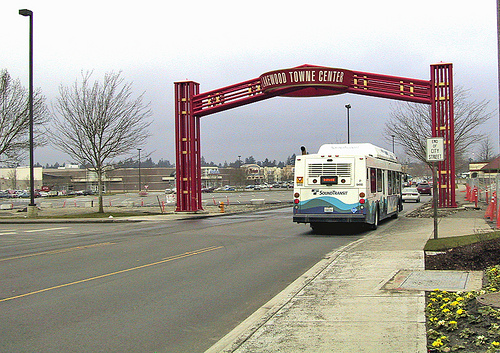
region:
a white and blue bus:
[294, 133, 397, 223]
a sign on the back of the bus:
[325, 171, 342, 182]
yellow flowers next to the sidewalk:
[429, 283, 499, 346]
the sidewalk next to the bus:
[297, 230, 403, 337]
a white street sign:
[428, 133, 447, 236]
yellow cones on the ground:
[53, 191, 198, 205]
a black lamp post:
[20, 8, 40, 213]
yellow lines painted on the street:
[16, 245, 215, 302]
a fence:
[466, 175, 495, 200]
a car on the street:
[404, 182, 419, 199]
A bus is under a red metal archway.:
[167, 57, 463, 233]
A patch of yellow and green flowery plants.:
[416, 265, 498, 351]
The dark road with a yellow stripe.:
[1, 207, 328, 351]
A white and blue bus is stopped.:
[287, 140, 415, 237]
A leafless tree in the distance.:
[46, 64, 161, 217]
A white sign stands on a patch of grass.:
[422, 132, 449, 250]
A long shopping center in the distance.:
[2, 163, 294, 191]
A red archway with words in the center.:
[171, 62, 459, 214]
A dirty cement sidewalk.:
[213, 208, 428, 351]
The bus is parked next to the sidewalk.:
[216, 135, 423, 351]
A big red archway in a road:
[172, 63, 455, 210]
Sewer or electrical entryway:
[400, 269, 469, 289]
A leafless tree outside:
[43, 66, 152, 210]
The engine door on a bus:
[306, 158, 353, 185]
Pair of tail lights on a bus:
[292, 191, 299, 206]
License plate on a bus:
[322, 205, 334, 213]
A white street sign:
[425, 135, 444, 161]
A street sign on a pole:
[425, 135, 445, 239]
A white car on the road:
[402, 185, 419, 201]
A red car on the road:
[415, 181, 431, 195]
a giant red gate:
[140, 32, 452, 239]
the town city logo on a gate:
[254, 65, 354, 93]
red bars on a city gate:
[205, 89, 249, 107]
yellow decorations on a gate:
[174, 93, 192, 118]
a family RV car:
[290, 133, 411, 235]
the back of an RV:
[281, 156, 361, 226]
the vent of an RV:
[298, 151, 353, 181]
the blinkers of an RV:
[344, 185, 375, 212]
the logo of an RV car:
[312, 179, 352, 207]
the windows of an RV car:
[368, 175, 396, 193]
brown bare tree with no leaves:
[67, 83, 152, 153]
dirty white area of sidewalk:
[326, 263, 356, 350]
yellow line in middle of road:
[57, 260, 155, 300]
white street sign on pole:
[424, 131, 453, 174]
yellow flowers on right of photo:
[429, 287, 452, 334]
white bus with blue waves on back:
[278, 143, 414, 232]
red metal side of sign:
[177, 76, 203, 216]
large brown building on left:
[29, 164, 126, 196]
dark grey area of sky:
[235, 121, 278, 149]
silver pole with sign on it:
[426, 164, 446, 229]